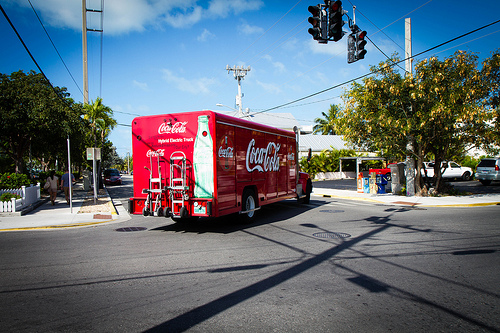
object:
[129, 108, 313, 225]
truck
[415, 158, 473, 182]
truck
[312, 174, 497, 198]
parking lot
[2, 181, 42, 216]
fence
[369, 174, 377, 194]
box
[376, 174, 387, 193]
box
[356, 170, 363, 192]
box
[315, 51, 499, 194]
tree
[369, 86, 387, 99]
flowers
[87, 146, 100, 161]
sign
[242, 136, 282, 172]
letters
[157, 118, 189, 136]
letters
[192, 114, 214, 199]
bottle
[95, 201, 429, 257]
intersection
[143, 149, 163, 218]
dolly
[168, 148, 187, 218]
dolly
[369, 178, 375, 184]
newspapers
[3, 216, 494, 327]
street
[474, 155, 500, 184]
truck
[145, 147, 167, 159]
logo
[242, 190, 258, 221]
wheel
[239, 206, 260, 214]
guard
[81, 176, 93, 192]
garbage can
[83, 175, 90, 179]
lid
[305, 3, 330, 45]
traffic light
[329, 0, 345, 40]
traffic light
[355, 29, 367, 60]
traffic light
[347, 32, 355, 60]
traffic light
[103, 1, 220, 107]
sky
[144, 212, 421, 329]
shadow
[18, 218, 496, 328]
ground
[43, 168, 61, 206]
person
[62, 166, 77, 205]
person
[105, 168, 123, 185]
car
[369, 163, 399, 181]
truck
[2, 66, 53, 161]
tree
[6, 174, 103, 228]
sidewalk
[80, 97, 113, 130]
tree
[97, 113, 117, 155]
tree